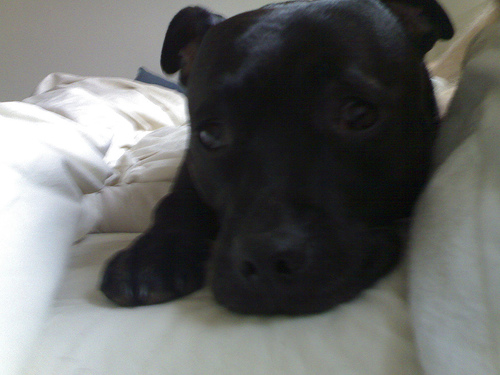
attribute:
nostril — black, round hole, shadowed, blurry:
[241, 259, 256, 282]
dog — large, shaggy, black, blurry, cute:
[96, 2, 456, 316]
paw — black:
[101, 250, 206, 305]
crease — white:
[71, 227, 145, 246]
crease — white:
[81, 177, 179, 194]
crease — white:
[136, 148, 161, 163]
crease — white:
[129, 153, 186, 173]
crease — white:
[144, 124, 191, 142]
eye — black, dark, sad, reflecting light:
[197, 120, 238, 150]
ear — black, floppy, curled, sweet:
[160, 5, 228, 88]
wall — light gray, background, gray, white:
[0, 0, 499, 102]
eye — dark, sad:
[339, 99, 378, 131]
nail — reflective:
[137, 283, 151, 301]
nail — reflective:
[121, 286, 134, 300]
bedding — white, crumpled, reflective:
[1, 70, 190, 374]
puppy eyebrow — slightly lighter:
[328, 63, 386, 94]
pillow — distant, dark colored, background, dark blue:
[133, 67, 184, 94]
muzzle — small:
[209, 181, 405, 316]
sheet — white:
[17, 232, 424, 374]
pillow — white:
[407, 20, 498, 374]